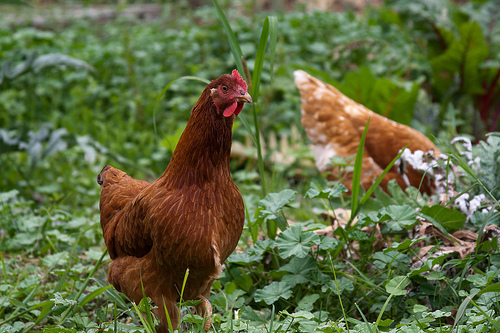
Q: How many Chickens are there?
A: 2.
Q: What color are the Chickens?
A: Brown.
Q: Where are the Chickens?
A: In a Field.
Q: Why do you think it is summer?
A: Plants are Green.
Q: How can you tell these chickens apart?
A: Different shades of Brown.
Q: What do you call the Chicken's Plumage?
A: Feathers.